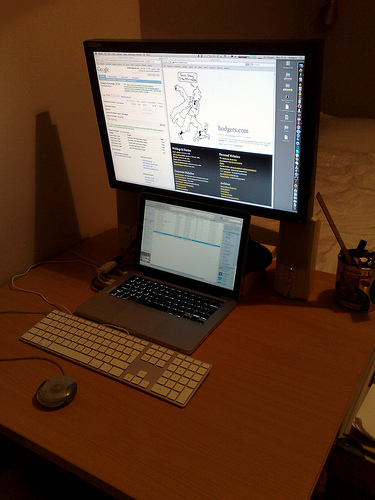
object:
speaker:
[277, 217, 312, 250]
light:
[290, 267, 293, 271]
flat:
[29, 298, 224, 434]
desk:
[242, 348, 294, 419]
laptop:
[76, 193, 251, 353]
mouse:
[35, 375, 77, 409]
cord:
[12, 257, 59, 307]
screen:
[94, 57, 301, 213]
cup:
[334, 240, 374, 313]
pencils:
[316, 192, 354, 265]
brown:
[244, 330, 271, 351]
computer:
[84, 36, 314, 279]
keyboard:
[18, 309, 211, 407]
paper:
[129, 82, 165, 119]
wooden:
[261, 326, 305, 346]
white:
[202, 80, 223, 104]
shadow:
[34, 134, 72, 190]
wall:
[21, 32, 56, 55]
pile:
[352, 384, 375, 453]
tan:
[19, 19, 83, 37]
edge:
[17, 454, 131, 500]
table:
[37, 416, 170, 491]